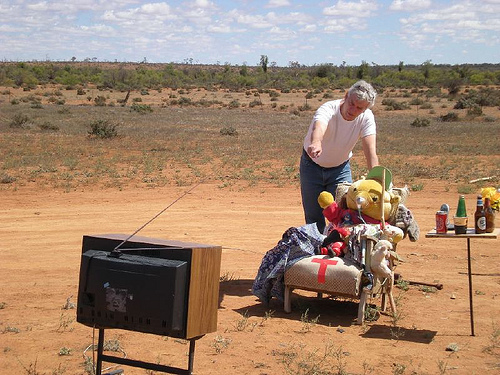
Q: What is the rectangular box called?
A: Television set.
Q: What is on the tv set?
A: Antenna.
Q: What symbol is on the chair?
A: Cross.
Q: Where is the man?
A: Desert.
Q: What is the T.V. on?
A: A stand.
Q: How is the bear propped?
A: Sitting.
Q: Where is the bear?
A: The chair.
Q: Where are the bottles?
A: On the table.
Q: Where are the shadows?
A: The ground.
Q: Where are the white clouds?
A: The sky.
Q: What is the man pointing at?
A: The T.V.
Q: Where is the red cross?
A: Chair.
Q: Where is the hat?
A: The bear's head.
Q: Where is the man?
A: The field.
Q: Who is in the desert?
A: The man.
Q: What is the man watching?
A: Television.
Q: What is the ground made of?
A: Dirt and grass.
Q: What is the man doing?
A: Pointing to a television.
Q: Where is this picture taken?
A: In the desert.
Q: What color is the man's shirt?
A: White.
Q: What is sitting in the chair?
A: A teddy bear.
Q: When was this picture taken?
A: Daytime.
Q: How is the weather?
A: Sunny.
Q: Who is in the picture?
A: A man.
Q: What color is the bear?
A: Yellow.